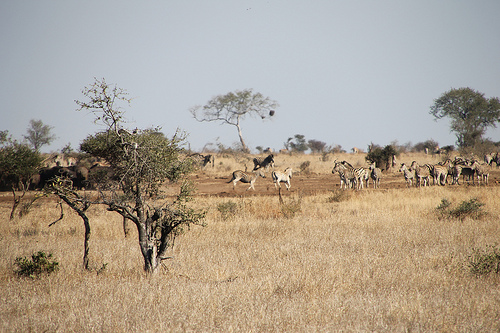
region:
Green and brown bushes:
[43, 130, 205, 263]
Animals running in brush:
[221, 148, 298, 201]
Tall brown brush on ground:
[213, 242, 429, 312]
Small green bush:
[13, 247, 70, 279]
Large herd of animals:
[324, 142, 491, 194]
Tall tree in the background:
[196, 95, 286, 142]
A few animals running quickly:
[199, 137, 301, 197]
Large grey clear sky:
[61, 49, 416, 129]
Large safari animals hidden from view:
[23, 151, 174, 198]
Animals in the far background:
[391, 137, 453, 159]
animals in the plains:
[152, 125, 498, 203]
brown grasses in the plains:
[1, 284, 496, 329]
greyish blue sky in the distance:
[9, 7, 487, 73]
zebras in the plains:
[319, 153, 371, 194]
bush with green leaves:
[11, 248, 69, 280]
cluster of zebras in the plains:
[394, 152, 496, 189]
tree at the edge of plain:
[429, 82, 498, 147]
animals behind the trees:
[52, 154, 99, 194]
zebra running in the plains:
[271, 162, 300, 192]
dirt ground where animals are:
[197, 178, 224, 195]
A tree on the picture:
[186, 86, 276, 156]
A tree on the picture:
[103, 72, 188, 277]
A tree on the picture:
[46, 171, 100, 277]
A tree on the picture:
[435, 82, 498, 153]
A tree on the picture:
[2, 130, 37, 227]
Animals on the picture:
[30, 143, 497, 203]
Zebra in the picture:
[229, 164, 266, 193]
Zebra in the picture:
[269, 165, 296, 191]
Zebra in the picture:
[330, 161, 365, 188]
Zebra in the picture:
[249, 151, 277, 173]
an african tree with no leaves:
[188, 77, 272, 144]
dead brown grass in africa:
[243, 253, 337, 325]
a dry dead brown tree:
[88, 140, 193, 270]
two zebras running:
[227, 150, 299, 195]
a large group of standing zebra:
[333, 143, 489, 198]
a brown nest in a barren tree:
[262, 107, 279, 119]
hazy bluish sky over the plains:
[283, 63, 376, 119]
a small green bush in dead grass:
[12, 242, 57, 280]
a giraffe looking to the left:
[331, 159, 361, 184]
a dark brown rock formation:
[14, 155, 121, 189]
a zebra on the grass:
[328, 156, 370, 196]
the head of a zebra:
[328, 159, 341, 181]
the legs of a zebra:
[338, 177, 366, 192]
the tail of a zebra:
[223, 170, 235, 186]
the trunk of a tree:
[140, 246, 166, 279]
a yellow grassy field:
[0, 149, 497, 331]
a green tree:
[76, 117, 198, 179]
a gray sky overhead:
[0, 0, 497, 150]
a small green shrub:
[12, 247, 69, 293]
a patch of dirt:
[124, 165, 494, 200]